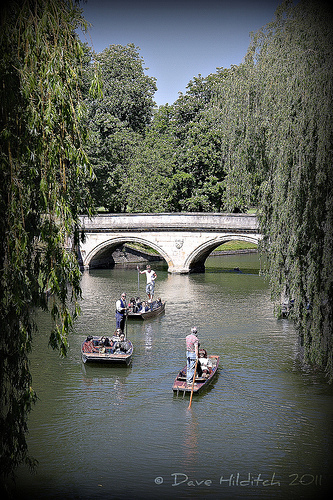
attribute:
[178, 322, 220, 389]
man — standing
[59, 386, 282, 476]
water — beautiful, green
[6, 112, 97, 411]
trees — hanging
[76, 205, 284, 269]
bridge — white, grey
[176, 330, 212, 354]
shirt — blue, pink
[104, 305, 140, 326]
shirt — white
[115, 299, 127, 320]
vest — blue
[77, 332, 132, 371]
lady — sitting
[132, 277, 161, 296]
shorts — blue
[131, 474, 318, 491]
sign — copyright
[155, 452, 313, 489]
letters — white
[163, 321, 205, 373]
person — standing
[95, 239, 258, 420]
boats — traveling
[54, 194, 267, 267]
bridge — stone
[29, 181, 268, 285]
bridge — stone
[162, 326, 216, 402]
man — standing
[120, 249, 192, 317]
man — standing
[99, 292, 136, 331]
man — standing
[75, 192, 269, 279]
bridges — gray, cement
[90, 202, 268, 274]
bridge — stone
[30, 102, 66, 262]
leaves — green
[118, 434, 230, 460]
water — murky, river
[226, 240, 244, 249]
lawn — grass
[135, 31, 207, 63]
blue — sky